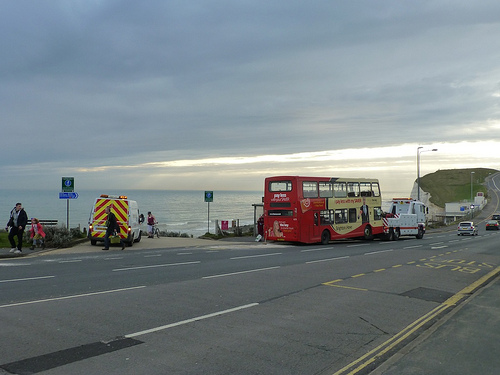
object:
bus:
[262, 175, 385, 246]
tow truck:
[381, 197, 430, 241]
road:
[0, 244, 499, 373]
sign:
[62, 177, 75, 192]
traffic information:
[58, 192, 79, 199]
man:
[4, 202, 28, 254]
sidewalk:
[0, 243, 52, 259]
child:
[28, 217, 47, 250]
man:
[146, 211, 157, 239]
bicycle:
[147, 222, 161, 239]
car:
[457, 220, 479, 236]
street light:
[416, 146, 438, 198]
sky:
[2, 0, 499, 172]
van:
[86, 194, 146, 247]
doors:
[93, 199, 130, 240]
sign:
[204, 191, 213, 203]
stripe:
[386, 227, 419, 229]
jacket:
[29, 224, 46, 239]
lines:
[332, 268, 500, 375]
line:
[123, 300, 260, 337]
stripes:
[115, 200, 127, 213]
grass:
[433, 169, 468, 197]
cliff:
[411, 168, 440, 198]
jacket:
[6, 207, 28, 230]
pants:
[7, 225, 24, 251]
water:
[161, 188, 201, 237]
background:
[0, 0, 499, 237]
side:
[412, 181, 444, 226]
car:
[486, 218, 500, 231]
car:
[490, 212, 500, 221]